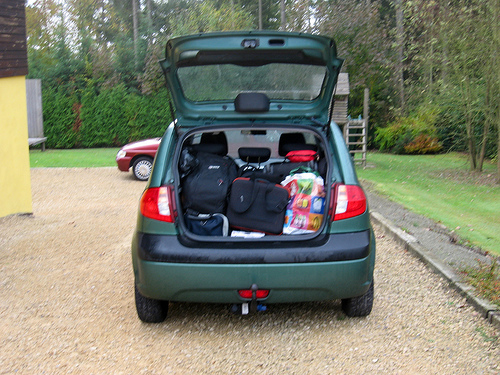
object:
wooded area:
[22, 2, 500, 156]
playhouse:
[313, 73, 372, 165]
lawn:
[369, 149, 500, 247]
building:
[1, 0, 42, 223]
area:
[447, 188, 496, 215]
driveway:
[3, 165, 498, 373]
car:
[114, 136, 161, 181]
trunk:
[164, 38, 351, 255]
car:
[129, 35, 379, 322]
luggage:
[182, 151, 325, 235]